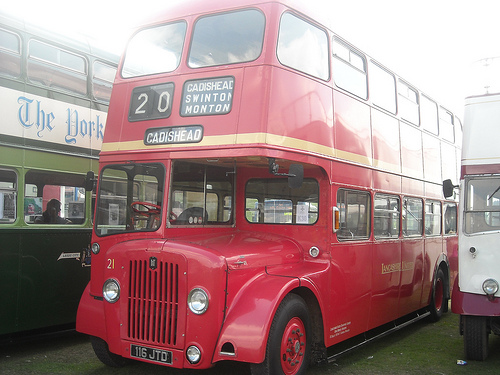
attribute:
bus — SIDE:
[264, 1, 462, 371]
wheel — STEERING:
[126, 197, 179, 220]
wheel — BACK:
[428, 262, 448, 319]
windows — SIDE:
[333, 176, 456, 237]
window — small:
[234, 171, 340, 231]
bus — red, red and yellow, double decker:
[71, 8, 458, 355]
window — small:
[330, 172, 379, 244]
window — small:
[371, 185, 416, 240]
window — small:
[392, 180, 428, 242]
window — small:
[422, 193, 449, 239]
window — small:
[431, 190, 460, 250]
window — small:
[320, 30, 373, 103]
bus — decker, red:
[95, 5, 472, 368]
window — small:
[357, 52, 403, 117]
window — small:
[390, 77, 422, 130]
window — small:
[166, 150, 237, 225]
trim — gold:
[81, 120, 474, 192]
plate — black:
[122, 346, 179, 366]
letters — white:
[120, 340, 180, 364]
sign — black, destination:
[141, 120, 210, 150]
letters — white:
[140, 126, 207, 142]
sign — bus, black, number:
[120, 73, 190, 116]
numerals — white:
[120, 76, 177, 119]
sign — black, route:
[178, 73, 238, 112]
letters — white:
[182, 77, 231, 109]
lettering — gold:
[377, 250, 437, 285]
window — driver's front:
[96, 163, 162, 235]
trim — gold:
[97, 139, 457, 188]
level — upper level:
[99, 0, 459, 179]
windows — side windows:
[336, 186, 459, 239]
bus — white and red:
[454, 91, 499, 354]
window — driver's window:
[99, 164, 159, 234]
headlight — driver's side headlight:
[102, 275, 121, 300]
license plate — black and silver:
[130, 340, 170, 363]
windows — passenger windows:
[372, 192, 456, 239]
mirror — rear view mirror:
[441, 176, 451, 196]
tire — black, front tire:
[248, 292, 314, 373]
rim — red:
[279, 316, 304, 372]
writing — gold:
[379, 255, 420, 273]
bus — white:
[447, 88, 498, 357]